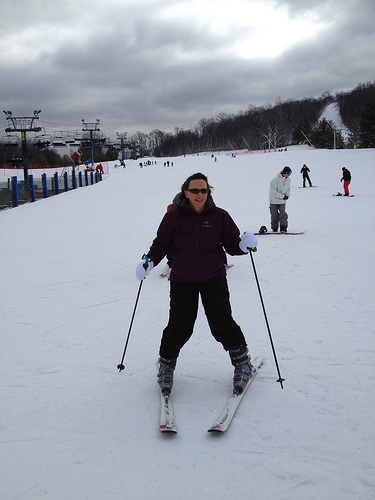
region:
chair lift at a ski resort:
[0, 103, 147, 159]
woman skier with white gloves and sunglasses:
[107, 167, 291, 444]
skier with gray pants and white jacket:
[247, 159, 308, 237]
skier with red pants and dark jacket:
[330, 164, 359, 201]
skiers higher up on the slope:
[120, 150, 264, 170]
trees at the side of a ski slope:
[182, 96, 318, 143]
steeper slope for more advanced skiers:
[315, 93, 354, 147]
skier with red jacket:
[88, 158, 108, 179]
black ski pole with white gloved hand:
[112, 250, 154, 376]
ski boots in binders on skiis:
[149, 340, 258, 397]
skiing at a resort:
[12, 96, 362, 320]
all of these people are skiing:
[134, 142, 300, 169]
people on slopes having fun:
[175, 147, 363, 284]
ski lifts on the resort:
[3, 102, 149, 151]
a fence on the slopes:
[5, 157, 104, 205]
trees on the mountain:
[184, 107, 316, 146]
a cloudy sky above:
[30, 18, 289, 103]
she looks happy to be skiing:
[152, 173, 251, 437]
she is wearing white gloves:
[126, 235, 255, 288]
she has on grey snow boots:
[149, 350, 259, 390]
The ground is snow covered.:
[21, 165, 370, 424]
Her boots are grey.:
[146, 355, 283, 462]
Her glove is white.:
[134, 255, 167, 283]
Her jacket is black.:
[150, 196, 245, 286]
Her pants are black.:
[154, 269, 241, 366]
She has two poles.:
[91, 166, 313, 418]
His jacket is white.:
[267, 172, 295, 202]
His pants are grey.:
[264, 202, 292, 233]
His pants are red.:
[339, 181, 349, 195]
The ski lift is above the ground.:
[9, 110, 159, 163]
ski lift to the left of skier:
[0, 110, 140, 191]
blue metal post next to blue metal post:
[11, 176, 17, 208]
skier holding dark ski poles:
[244, 232, 293, 390]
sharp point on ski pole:
[279, 380, 285, 389]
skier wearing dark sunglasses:
[185, 187, 209, 193]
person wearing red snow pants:
[338, 167, 351, 195]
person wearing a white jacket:
[269, 166, 293, 231]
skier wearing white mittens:
[238, 231, 260, 252]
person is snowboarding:
[296, 163, 319, 188]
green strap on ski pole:
[142, 253, 149, 264]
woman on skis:
[128, 162, 260, 387]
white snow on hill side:
[15, 232, 132, 342]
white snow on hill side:
[16, 340, 93, 401]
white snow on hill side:
[21, 402, 106, 459]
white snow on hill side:
[123, 437, 264, 488]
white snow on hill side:
[280, 390, 342, 460]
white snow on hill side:
[290, 263, 359, 353]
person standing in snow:
[267, 158, 297, 240]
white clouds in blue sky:
[13, 15, 106, 53]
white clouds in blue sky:
[144, 21, 238, 90]